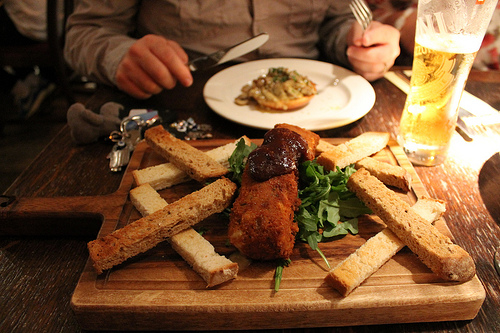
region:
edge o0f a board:
[131, 270, 181, 315]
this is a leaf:
[301, 194, 312, 206]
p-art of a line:
[173, 277, 218, 312]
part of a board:
[138, 292, 163, 312]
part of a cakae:
[200, 248, 228, 298]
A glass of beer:
[397, 0, 496, 162]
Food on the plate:
[204, 58, 375, 130]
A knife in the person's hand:
[111, 32, 268, 98]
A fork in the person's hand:
[344, 1, 400, 81]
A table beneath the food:
[0, 66, 499, 328]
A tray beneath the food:
[0, 139, 485, 329]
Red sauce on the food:
[248, 127, 307, 177]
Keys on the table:
[67, 101, 209, 169]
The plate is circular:
[205, 59, 375, 128]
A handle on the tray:
[3, 196, 102, 235]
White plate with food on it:
[202, 56, 376, 130]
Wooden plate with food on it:
[70, 123, 486, 332]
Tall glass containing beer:
[396, 0, 498, 170]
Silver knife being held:
[185, 33, 268, 77]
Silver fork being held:
[343, 0, 401, 80]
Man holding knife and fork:
[60, 0, 401, 100]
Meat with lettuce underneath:
[225, 123, 370, 266]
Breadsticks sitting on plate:
[86, 179, 242, 289]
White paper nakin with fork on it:
[382, 63, 498, 143]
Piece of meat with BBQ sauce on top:
[231, 123, 320, 265]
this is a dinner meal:
[23, 29, 485, 281]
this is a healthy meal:
[46, 90, 486, 291]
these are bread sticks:
[105, 194, 237, 286]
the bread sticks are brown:
[110, 179, 195, 274]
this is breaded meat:
[218, 145, 303, 265]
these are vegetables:
[295, 175, 380, 237]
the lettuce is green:
[290, 165, 340, 220]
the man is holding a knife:
[80, 30, 275, 120]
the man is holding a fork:
[326, 21, 407, 55]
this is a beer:
[417, 8, 472, 223]